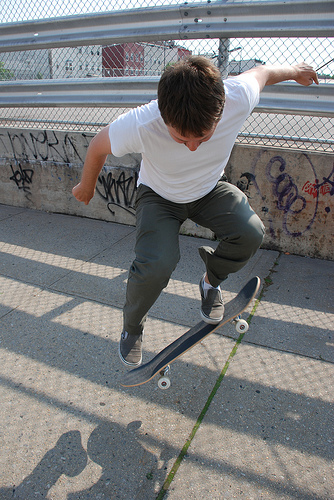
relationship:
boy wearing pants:
[67, 36, 318, 395] [123, 182, 280, 325]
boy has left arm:
[67, 36, 318, 395] [242, 54, 332, 112]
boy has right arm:
[67, 36, 318, 395] [57, 122, 115, 209]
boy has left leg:
[67, 36, 318, 395] [197, 191, 264, 297]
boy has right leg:
[67, 36, 318, 395] [116, 192, 179, 341]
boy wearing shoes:
[67, 36, 318, 395] [105, 272, 256, 363]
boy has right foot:
[67, 36, 318, 395] [104, 322, 160, 369]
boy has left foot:
[67, 36, 318, 395] [195, 272, 234, 319]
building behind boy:
[0, 46, 104, 78] [67, 36, 318, 395]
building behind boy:
[105, 43, 144, 75] [67, 36, 318, 395]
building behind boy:
[140, 45, 174, 75] [67, 36, 318, 395]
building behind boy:
[178, 44, 200, 61] [67, 36, 318, 395]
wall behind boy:
[0, 107, 333, 229] [67, 36, 318, 395]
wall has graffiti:
[0, 107, 333, 229] [6, 133, 82, 165]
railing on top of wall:
[2, 17, 333, 111] [0, 107, 333, 229]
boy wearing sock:
[67, 36, 318, 395] [199, 269, 220, 294]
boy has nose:
[67, 36, 318, 395] [182, 135, 207, 152]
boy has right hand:
[67, 36, 318, 395] [69, 178, 101, 206]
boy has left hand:
[67, 36, 318, 395] [295, 59, 320, 95]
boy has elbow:
[67, 36, 318, 395] [259, 65, 283, 88]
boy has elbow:
[67, 36, 318, 395] [86, 121, 120, 162]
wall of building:
[5, 49, 55, 78] [0, 46, 104, 78]